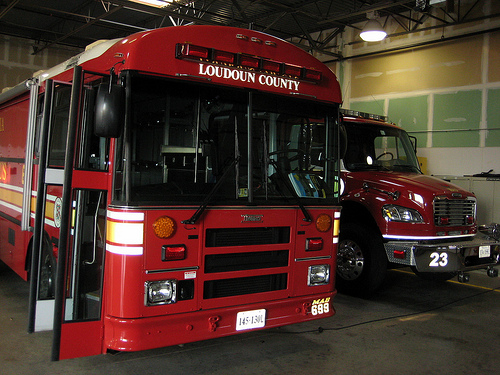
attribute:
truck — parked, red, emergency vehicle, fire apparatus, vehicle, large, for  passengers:
[1, 22, 344, 359]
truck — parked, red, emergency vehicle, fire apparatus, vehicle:
[337, 105, 499, 293]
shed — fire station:
[2, 2, 499, 374]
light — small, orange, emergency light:
[152, 216, 178, 240]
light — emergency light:
[314, 212, 333, 233]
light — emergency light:
[160, 243, 188, 264]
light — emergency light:
[303, 235, 325, 251]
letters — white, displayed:
[196, 60, 302, 94]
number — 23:
[427, 249, 451, 269]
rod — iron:
[305, 0, 424, 27]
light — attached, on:
[356, 12, 388, 43]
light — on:
[128, 0, 180, 10]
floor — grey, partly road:
[3, 252, 500, 374]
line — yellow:
[393, 266, 499, 295]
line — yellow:
[376, 311, 437, 331]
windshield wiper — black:
[182, 152, 249, 226]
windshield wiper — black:
[269, 155, 313, 221]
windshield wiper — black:
[346, 161, 387, 172]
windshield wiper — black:
[393, 162, 422, 173]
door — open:
[50, 63, 115, 362]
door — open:
[25, 76, 88, 336]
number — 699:
[310, 300, 334, 317]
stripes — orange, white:
[0, 181, 146, 257]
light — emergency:
[340, 106, 390, 124]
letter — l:
[197, 59, 207, 76]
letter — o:
[205, 63, 216, 77]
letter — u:
[214, 64, 224, 77]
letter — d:
[223, 66, 233, 79]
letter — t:
[287, 78, 297, 91]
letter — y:
[293, 78, 304, 92]